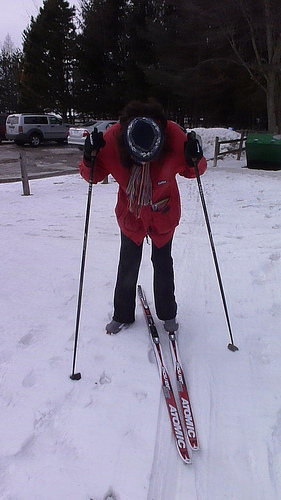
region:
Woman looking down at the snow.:
[47, 79, 251, 353]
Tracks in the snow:
[93, 372, 176, 438]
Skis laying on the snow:
[134, 287, 202, 461]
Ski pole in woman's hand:
[70, 180, 85, 397]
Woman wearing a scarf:
[116, 145, 160, 224]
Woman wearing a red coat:
[63, 125, 219, 264]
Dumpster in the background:
[227, 129, 279, 162]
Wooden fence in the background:
[0, 151, 38, 201]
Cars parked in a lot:
[2, 97, 116, 142]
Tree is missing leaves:
[146, 13, 273, 78]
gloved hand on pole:
[79, 126, 106, 180]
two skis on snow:
[151, 346, 212, 462]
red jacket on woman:
[107, 122, 194, 247]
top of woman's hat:
[126, 115, 167, 162]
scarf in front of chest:
[123, 161, 158, 216]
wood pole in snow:
[16, 149, 39, 201]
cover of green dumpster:
[247, 130, 275, 146]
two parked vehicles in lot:
[28, 112, 101, 148]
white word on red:
[179, 394, 200, 439]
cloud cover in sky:
[4, 3, 27, 33]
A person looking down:
[77, 100, 205, 333]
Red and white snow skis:
[137, 284, 199, 462]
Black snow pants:
[112, 231, 176, 320]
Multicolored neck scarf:
[125, 162, 151, 216]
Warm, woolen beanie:
[126, 116, 160, 158]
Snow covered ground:
[0, 127, 279, 499]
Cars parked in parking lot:
[0, 114, 118, 147]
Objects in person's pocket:
[151, 197, 170, 211]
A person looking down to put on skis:
[69, 103, 239, 463]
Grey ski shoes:
[105, 317, 178, 333]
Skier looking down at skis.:
[58, 94, 238, 466]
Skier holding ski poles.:
[68, 96, 250, 387]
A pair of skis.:
[128, 274, 212, 471]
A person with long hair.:
[101, 89, 181, 174]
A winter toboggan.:
[108, 109, 175, 174]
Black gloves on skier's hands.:
[79, 117, 203, 168]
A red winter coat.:
[76, 118, 206, 240]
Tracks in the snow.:
[16, 345, 263, 498]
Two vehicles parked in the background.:
[8, 98, 118, 152]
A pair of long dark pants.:
[106, 206, 184, 324]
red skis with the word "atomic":
[138, 275, 222, 464]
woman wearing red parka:
[85, 98, 201, 344]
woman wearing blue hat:
[89, 93, 183, 428]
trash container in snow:
[247, 118, 278, 177]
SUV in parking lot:
[5, 104, 70, 143]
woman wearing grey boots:
[76, 103, 207, 335]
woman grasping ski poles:
[54, 106, 212, 179]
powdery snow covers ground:
[0, 177, 278, 497]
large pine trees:
[9, 1, 266, 121]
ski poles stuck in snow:
[3, 138, 78, 168]